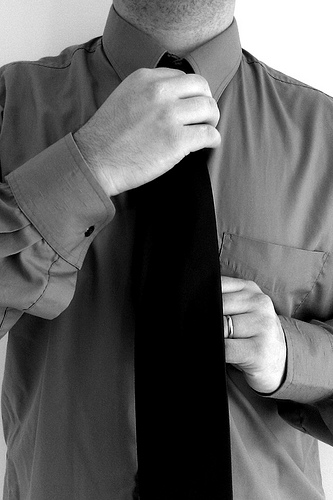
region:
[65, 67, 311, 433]
man wearing tie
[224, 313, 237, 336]
man wearing ring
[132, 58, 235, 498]
it is a black tie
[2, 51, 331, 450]
man wearing full hand shirt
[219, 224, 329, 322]
it is a pocket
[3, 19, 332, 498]
it is a brown color shirt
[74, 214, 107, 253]
it is a shirt batan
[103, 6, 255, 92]
it is a collar type shirt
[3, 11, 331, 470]
it is a formal shirt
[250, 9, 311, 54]
background is white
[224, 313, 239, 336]
Wedding ring on man hand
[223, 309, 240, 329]
man wearing a wedding a ring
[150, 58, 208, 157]
man fixing his tie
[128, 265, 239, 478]
Man wearing a black tie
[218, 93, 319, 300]
Man wearing a grey shirt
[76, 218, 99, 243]
Man with a button on his shirt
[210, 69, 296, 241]
Man wearing a dress shirt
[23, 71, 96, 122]
Shirt on a man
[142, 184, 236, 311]
Man with a black tie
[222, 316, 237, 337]
Man wearing a gold wedding ring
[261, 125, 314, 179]
Part of the man's shirt.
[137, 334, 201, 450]
Part of the black tie.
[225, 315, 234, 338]
A ring on the man's finger.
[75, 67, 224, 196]
The man's hand.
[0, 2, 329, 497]
A man fixing his tie.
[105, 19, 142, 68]
Part of the shirt collar.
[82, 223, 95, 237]
A small button on the cuff.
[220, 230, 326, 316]
Part of the shirt pocket.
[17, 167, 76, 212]
Part of the shirt cuff.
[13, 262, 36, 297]
Part of the shirt sleeve.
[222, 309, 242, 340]
Silver ring on mans hand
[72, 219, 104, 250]
Small button on cloth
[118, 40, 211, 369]
Black tie around neck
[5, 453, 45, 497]
Small grey peice of fabric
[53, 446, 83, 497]
Small grey peice of fabric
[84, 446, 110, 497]
Small grey peice of fabric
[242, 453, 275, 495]
Small grey peice of fabric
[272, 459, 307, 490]
Small grey peice of fabric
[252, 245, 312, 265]
Small grey peice of fabric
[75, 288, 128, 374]
Small grey peice of fabric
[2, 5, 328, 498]
man has a black tie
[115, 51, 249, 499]
a long black tie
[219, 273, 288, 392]
man wearing a ring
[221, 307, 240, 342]
a ring of gold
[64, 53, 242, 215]
a hand on a tie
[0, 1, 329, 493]
man holding a tie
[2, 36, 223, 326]
a right hand on a tie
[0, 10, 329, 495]
a black tie over a gray shirt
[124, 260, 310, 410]
fingers underneath a tie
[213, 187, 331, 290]
the pocket of a gray tie